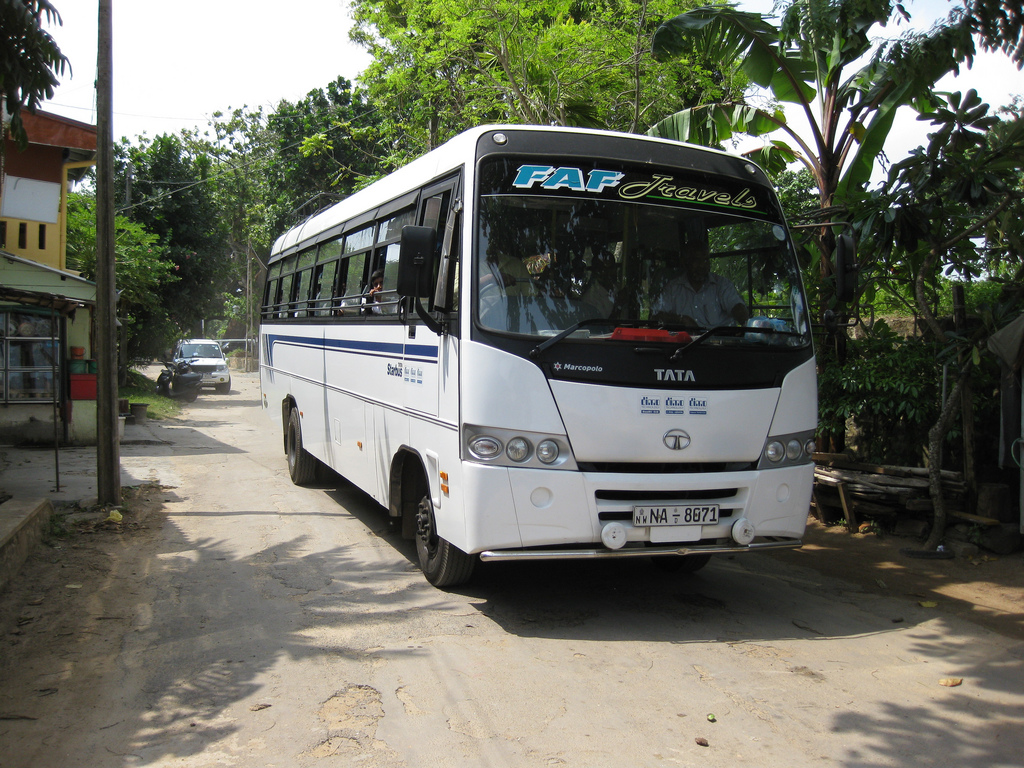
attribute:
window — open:
[364, 251, 386, 306]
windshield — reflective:
[470, 175, 805, 342]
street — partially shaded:
[11, 353, 1020, 764]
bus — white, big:
[236, 98, 839, 589]